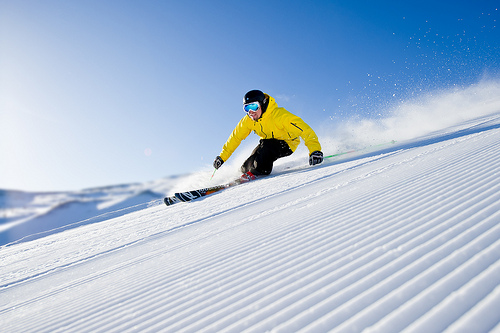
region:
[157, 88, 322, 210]
man in yellow jacket skiing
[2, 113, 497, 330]
rippled snow on the ground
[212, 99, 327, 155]
yellow jacket on the skiier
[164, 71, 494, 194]
residue of snow in the air from the skiier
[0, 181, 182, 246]
slopes in the distance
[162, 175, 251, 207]
the man's skiis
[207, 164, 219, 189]
skii pole in the man's right hand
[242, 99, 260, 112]
reflective skii goggles on the man's face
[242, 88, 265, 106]
black helmet on the man's head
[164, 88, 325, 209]
the skiier is going down a slope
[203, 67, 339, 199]
This is a person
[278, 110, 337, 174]
Hand of a person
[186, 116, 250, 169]
Hand of a person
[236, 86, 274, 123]
Head of a person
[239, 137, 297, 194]
Legs of a person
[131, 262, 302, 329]
This is lots of snow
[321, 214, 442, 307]
This is lots of snow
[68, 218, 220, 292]
This is lots of snow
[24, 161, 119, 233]
This is lots of snow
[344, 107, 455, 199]
This is lots of snow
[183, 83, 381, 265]
the man is skiing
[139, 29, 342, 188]
the man is skiing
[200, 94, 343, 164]
the jacket is yellow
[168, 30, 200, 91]
part of the sky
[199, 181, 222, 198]
part of a skate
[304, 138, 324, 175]
part of a glove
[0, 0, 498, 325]
guy skiing on the snow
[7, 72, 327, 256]
guy skiing near mountains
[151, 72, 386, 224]
guy on two ski boards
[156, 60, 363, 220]
guy wearing a black helmet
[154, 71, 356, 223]
guy wearing a ski mask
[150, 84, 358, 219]
guy wearing black gloves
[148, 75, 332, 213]
guy wearing black pants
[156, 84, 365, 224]
guy leaning to the side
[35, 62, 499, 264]
guy skiing fast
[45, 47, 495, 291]
guy skiing down the hill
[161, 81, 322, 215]
skier in white snow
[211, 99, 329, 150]
yellow jacket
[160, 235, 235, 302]
white tracks in hill side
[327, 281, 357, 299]
white tracks in hill side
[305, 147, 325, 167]
glove worn by human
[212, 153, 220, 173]
glove worn by human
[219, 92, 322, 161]
jacket worn by human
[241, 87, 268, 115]
helmet worn by human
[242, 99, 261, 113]
googles worn by human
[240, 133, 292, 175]
pants worn by human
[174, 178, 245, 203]
ski worn by human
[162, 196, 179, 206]
ski worn by human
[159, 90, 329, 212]
skiier moves down hill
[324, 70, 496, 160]
cloud of snow behind skier